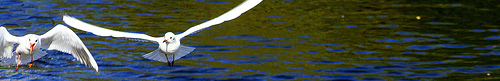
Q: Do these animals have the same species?
A: Yes, all the animals are birds.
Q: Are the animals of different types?
A: No, all the animals are birds.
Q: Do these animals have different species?
A: No, all the animals are birds.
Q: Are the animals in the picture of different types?
A: No, all the animals are birds.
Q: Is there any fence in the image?
A: No, there are no fences.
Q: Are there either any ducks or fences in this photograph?
A: No, there are no fences or ducks.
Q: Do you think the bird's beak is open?
A: Yes, the beak is open.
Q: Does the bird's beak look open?
A: Yes, the beak is open.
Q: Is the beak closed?
A: No, the beak is open.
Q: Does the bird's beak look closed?
A: No, the beak is open.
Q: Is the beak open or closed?
A: The beak is open.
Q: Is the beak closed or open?
A: The beak is open.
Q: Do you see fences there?
A: No, there are no fences.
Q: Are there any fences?
A: No, there are no fences.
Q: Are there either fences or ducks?
A: No, there are no fences or ducks.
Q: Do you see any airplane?
A: No, there are no airplanes.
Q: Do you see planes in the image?
A: No, there are no planes.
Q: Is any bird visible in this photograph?
A: Yes, there is a bird.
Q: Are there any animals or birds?
A: Yes, there is a bird.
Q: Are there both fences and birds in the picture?
A: No, there is a bird but no fences.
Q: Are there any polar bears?
A: No, there are no polar bears.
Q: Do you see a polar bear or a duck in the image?
A: No, there are no polar bears or ducks.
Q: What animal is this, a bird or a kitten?
A: This is a bird.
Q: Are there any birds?
A: Yes, there is a bird.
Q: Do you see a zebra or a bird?
A: Yes, there is a bird.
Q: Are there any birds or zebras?
A: Yes, there is a bird.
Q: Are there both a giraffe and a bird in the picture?
A: No, there is a bird but no giraffes.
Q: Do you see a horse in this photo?
A: No, there are no horses.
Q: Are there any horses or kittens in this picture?
A: No, there are no horses or kittens.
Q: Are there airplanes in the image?
A: No, there are no airplanes.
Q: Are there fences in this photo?
A: No, there are no fences.